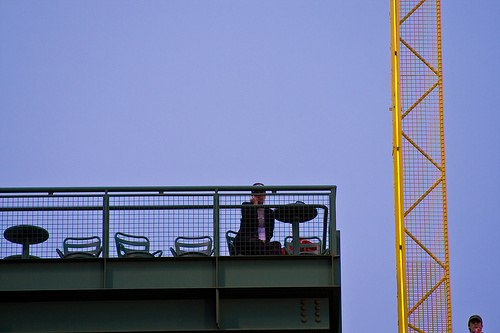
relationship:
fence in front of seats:
[0, 185, 337, 260] [56, 229, 328, 259]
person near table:
[231, 182, 282, 254] [275, 206, 317, 255]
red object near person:
[282, 238, 318, 255] [231, 182, 282, 254]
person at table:
[231, 182, 282, 254] [275, 206, 317, 255]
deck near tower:
[0, 185, 343, 332] [388, 1, 451, 332]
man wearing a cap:
[469, 314, 485, 332] [468, 315, 482, 323]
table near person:
[275, 206, 317, 255] [231, 182, 282, 254]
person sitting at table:
[231, 182, 282, 254] [275, 206, 317, 255]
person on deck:
[231, 182, 282, 254] [0, 185, 343, 332]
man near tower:
[469, 314, 485, 332] [388, 1, 451, 332]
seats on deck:
[56, 229, 328, 259] [0, 185, 343, 332]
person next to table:
[231, 182, 282, 254] [275, 206, 317, 255]